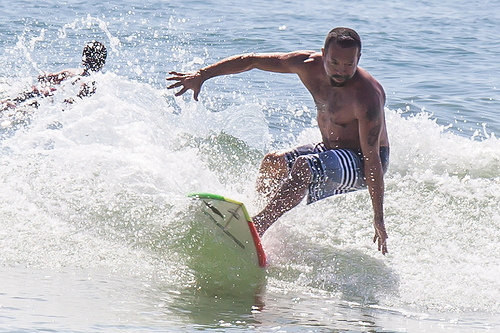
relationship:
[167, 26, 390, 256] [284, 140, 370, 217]
man in shorts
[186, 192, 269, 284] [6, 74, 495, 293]
surfboard coming out wave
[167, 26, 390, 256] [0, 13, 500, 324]
man behind wave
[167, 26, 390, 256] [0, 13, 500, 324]
man riding wave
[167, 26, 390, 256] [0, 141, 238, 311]
man kicking up splash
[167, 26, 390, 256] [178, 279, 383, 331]
man has a reflection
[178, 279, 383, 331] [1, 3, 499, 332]
reflection on water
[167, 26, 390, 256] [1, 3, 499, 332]
man in water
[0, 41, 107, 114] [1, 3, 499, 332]
man in water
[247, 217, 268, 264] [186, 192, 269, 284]
rim on surfboard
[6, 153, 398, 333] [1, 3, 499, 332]
reflection on water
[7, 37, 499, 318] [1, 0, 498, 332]
splash in water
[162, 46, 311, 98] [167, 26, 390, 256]
arm on a man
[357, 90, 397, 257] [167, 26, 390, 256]
arm on a man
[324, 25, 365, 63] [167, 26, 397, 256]
hair on a man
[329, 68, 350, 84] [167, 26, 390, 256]
moustache on a man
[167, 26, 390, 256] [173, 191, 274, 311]
man on a surfboard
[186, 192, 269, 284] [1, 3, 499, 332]
surfboard in water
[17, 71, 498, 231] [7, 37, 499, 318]
cap on wave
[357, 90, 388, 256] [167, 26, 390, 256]
arm of man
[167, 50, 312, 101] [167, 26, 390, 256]
arm of man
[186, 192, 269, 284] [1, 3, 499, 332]
surfboard on water